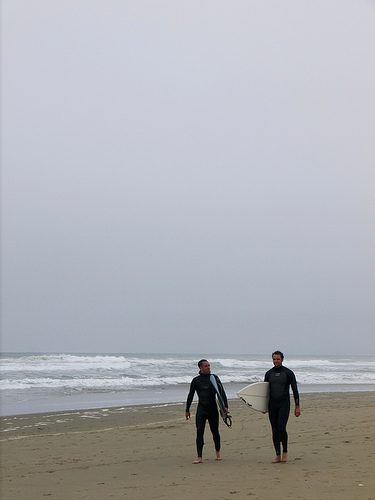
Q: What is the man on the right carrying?
A: A surfboard.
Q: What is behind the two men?
A: The ocean.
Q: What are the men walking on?
A: The beach sand.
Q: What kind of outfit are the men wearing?
A: Black wetsuits.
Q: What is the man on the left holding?
A: A surfboard.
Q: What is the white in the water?
A: Waves.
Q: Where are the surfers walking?
A: In the sand.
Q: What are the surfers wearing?
A: Black wetsuits.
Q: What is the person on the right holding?
A: A surfboard.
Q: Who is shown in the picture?
A: Two surfers.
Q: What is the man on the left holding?
A: A surfboard.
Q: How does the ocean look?
A: Rough.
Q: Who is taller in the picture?
A: The man on the right.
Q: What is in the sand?
A: Footprints.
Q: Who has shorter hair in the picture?
A: The surfer on the left.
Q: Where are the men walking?
A: On the beach.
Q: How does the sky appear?
A: Overcast.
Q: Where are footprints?
A: On the sand.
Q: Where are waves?
A: In the ocean.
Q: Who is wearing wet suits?
A: The surfers.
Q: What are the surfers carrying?
A: Surfboards.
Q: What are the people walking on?
A: Sand.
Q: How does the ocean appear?
A: Rough.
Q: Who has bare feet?
A: Both surfers.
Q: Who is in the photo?
A: Two men with surfboards?.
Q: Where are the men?
A: On the beach.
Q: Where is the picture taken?
A: Beach.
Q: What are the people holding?
A: Surfboards.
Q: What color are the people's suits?
A: Black.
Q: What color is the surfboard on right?
A: White.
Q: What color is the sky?
A: Grey.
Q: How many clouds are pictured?
A: None.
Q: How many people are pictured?
A: Two.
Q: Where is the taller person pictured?
A: Right.